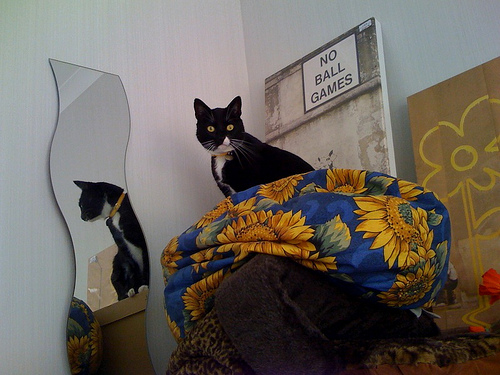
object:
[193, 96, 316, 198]
cat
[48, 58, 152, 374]
mirror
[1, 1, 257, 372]
wall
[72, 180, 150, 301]
reflection of cat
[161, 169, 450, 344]
blanket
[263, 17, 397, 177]
board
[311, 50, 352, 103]
writing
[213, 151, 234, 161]
collar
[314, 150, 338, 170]
drawing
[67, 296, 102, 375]
blanket's reflection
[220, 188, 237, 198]
leg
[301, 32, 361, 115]
sign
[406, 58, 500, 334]
cardboard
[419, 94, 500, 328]
flower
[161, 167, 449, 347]
sunflowers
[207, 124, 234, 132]
eyes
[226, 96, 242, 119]
ear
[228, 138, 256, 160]
whiskers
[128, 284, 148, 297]
paws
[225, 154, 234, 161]
identification tag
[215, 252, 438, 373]
pillow